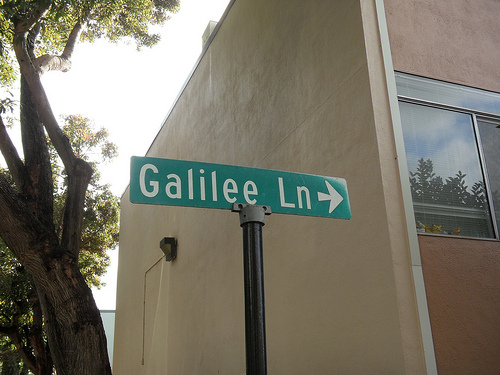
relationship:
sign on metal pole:
[128, 154, 350, 219] [239, 206, 268, 375]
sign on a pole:
[129, 156, 352, 220] [240, 203, 267, 372]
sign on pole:
[128, 154, 350, 219] [237, 225, 272, 368]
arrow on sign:
[309, 155, 372, 249] [96, 111, 391, 258]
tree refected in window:
[407, 152, 497, 245] [390, 52, 498, 260]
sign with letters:
[129, 156, 352, 220] [139, 164, 344, 214]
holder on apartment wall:
[160, 237, 176, 262] [116, 10, 435, 373]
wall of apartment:
[116, 10, 435, 373] [110, 6, 487, 365]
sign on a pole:
[128, 154, 350, 219] [241, 225, 270, 372]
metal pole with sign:
[239, 206, 268, 375] [128, 154, 350, 219]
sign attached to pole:
[128, 154, 350, 219] [230, 200, 277, 374]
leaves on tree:
[4, 114, 118, 291] [2, 2, 178, 373]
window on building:
[393, 70, 500, 241] [113, 0, 499, 373]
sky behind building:
[0, 1, 233, 311] [131, 44, 451, 348]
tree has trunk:
[2, 2, 178, 373] [11, 79, 126, 365]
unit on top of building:
[198, 19, 219, 53] [113, 0, 499, 373]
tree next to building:
[0, 0, 181, 375] [57, 19, 483, 373]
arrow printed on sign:
[318, 180, 344, 214] [128, 154, 350, 219]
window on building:
[391, 65, 498, 245] [113, 0, 499, 373]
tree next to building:
[2, 2, 178, 373] [113, 0, 499, 373]